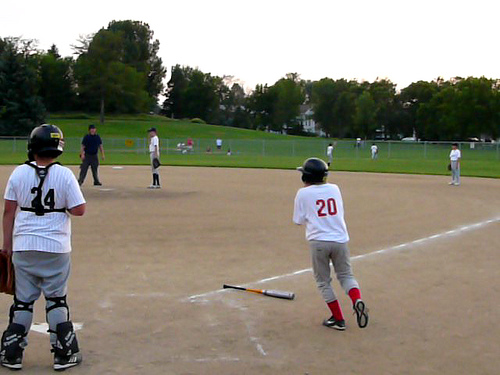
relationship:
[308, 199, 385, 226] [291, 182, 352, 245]
20 on back of jersey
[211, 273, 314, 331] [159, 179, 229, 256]
bat rests on dirt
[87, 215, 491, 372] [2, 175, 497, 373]
lines on dirt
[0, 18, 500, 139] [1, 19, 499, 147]
trees have leaves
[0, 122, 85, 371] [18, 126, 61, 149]
boy wears helmet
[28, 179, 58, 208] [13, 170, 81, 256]
24 on back of shirt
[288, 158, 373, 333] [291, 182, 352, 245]
baseball player wears jersey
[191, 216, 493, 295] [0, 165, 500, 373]
lines painted on ground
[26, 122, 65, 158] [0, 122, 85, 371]
helmet worn by boy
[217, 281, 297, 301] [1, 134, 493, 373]
bat rests on clay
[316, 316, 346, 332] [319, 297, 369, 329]
sneaker in pair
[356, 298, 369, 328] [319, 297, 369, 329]
sneaker in pair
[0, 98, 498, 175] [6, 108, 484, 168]
grass in park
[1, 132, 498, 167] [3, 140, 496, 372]
fence around baseball field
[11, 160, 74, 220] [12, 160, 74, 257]
chest mask around chest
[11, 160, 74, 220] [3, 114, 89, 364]
chest mask around boy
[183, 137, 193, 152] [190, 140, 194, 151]
person sitting on chair